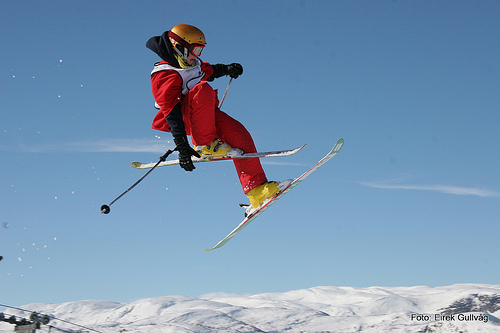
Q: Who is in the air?
A: The skier.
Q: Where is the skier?
A: Above the mountain.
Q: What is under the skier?
A: Snow.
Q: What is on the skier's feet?
A: Skis.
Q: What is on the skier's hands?
A: Gloves.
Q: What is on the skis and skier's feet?
A: Boots.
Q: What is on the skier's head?
A: A helmet.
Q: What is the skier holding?
A: Ski poles.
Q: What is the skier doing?
A: Jumping.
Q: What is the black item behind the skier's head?
A: A hood.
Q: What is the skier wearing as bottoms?
A: Red pants.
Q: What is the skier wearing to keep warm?
A: A jacket.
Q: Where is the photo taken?
A: The mountains.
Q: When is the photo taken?
A: Winter.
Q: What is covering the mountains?
A: Snow.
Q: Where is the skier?
A: In the air.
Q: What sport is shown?
A: Skiing.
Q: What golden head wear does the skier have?
A: A helmet.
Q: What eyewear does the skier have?
A: Goggles.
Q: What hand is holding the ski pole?
A: The left.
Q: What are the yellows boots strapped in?
A: Skis.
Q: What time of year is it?
A: Winter.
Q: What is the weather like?
A: Cold.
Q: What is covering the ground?
A: Snow.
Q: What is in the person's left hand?
A: A ski pole.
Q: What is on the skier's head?
A: A helmet.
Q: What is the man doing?
A: Skiing.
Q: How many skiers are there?
A: One.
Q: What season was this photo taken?
A: Winter.